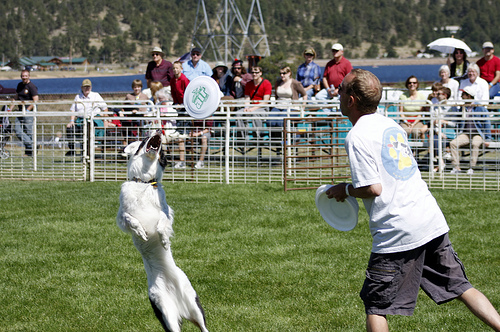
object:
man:
[324, 66, 500, 331]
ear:
[345, 95, 355, 107]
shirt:
[343, 112, 453, 254]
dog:
[120, 133, 212, 331]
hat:
[79, 76, 94, 88]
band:
[345, 181, 351, 198]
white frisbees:
[314, 184, 361, 232]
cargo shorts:
[358, 234, 473, 317]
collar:
[129, 177, 165, 186]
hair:
[342, 68, 385, 113]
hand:
[325, 181, 348, 204]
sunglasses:
[336, 80, 363, 102]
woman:
[449, 47, 470, 79]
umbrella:
[427, 34, 473, 58]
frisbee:
[181, 73, 223, 122]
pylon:
[186, 0, 273, 68]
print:
[192, 85, 209, 108]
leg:
[358, 248, 400, 331]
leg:
[422, 244, 500, 330]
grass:
[2, 180, 500, 331]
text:
[189, 87, 208, 108]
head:
[120, 130, 170, 182]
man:
[65, 79, 111, 157]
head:
[77, 78, 94, 97]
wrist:
[343, 182, 359, 200]